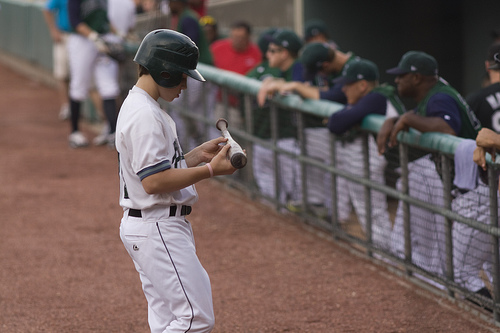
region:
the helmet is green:
[128, 16, 223, 110]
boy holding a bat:
[108, 30, 285, 223]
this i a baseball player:
[96, 28, 242, 319]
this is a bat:
[214, 110, 253, 167]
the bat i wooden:
[215, 109, 248, 183]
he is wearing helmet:
[137, 30, 201, 82]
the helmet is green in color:
[141, 32, 201, 72]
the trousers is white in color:
[153, 215, 200, 330]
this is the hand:
[174, 168, 198, 183]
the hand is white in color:
[169, 170, 191, 183]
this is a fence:
[373, 140, 453, 270]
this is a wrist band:
[201, 158, 217, 179]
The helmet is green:
[133, 27, 204, 87]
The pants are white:
[117, 209, 212, 331]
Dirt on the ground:
[17, 233, 117, 318]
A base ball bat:
[213, 116, 243, 166]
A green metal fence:
[298, 100, 410, 260]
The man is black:
[373, 50, 453, 148]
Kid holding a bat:
[113, 28, 244, 329]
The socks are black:
[66, 95, 114, 133]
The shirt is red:
[210, 37, 260, 103]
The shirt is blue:
[45, 0, 70, 33]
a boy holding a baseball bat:
[97, 17, 254, 328]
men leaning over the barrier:
[237, 19, 496, 300]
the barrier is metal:
[3, 2, 496, 307]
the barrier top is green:
[111, 6, 497, 176]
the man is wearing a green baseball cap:
[383, 50, 441, 79]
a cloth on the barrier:
[449, 137, 484, 194]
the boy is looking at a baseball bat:
[110, 20, 250, 328]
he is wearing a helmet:
[127, 22, 208, 92]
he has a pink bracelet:
[200, 159, 218, 180]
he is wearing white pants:
[110, 209, 213, 331]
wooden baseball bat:
[211, 112, 247, 167]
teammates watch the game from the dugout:
[112, 11, 494, 306]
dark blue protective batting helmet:
[130, 22, 210, 87]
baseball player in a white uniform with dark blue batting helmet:
[110, 25, 221, 327]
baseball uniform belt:
[121, 203, 190, 219]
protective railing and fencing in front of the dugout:
[185, 57, 495, 325]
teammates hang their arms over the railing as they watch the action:
[253, 26, 496, 138]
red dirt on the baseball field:
[6, 54, 474, 329]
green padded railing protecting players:
[191, 60, 498, 163]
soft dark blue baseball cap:
[386, 49, 443, 77]